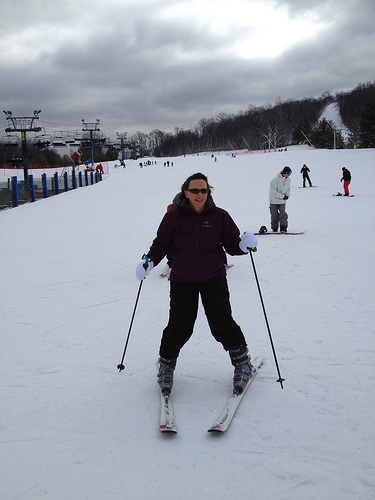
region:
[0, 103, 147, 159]
chair lift at a ski resort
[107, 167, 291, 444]
woman skier with white gloves and sunglasses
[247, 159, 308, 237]
skier with gray pants and white jacket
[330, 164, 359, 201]
skier with red pants and dark jacket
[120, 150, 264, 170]
skiers higher up on the slope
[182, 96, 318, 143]
trees at the side of a ski slope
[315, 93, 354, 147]
steeper slope for more advanced skiers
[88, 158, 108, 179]
skier with red jacket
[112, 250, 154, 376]
black ski pole with white gloved hand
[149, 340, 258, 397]
ski boots in binders on skiis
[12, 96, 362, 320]
skiing at a resort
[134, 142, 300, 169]
all of these people are skiing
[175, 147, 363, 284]
people on slopes having fun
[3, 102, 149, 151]
ski lifts on the resort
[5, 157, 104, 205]
a fence on the slopes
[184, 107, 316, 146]
trees on the mountain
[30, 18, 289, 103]
a cloudy sky above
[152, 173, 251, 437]
she looks happy to be skiing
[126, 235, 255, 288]
she is wearing white gloves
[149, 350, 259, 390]
she has on grey snow boots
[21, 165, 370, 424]
The ground is snow covered.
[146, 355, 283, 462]
Her boots are grey.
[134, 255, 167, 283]
Her glove is white.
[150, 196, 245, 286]
Her jacket is black.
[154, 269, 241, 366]
Her pants are black.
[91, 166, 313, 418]
She has two poles.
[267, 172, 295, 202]
His jacket is white.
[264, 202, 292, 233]
His pants are grey.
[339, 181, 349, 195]
His pants are red.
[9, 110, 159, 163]
The ski lift is above the ground.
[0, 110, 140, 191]
ski lift to the left of skier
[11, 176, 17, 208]
blue metal post next to blue metal post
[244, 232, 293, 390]
skier holding dark ski poles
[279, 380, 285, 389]
sharp point on ski pole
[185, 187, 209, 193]
skier wearing dark sunglasses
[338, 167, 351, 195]
person wearing red snow pants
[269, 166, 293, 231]
person wearing a white jacket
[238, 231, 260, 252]
skier wearing white mittens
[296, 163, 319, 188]
person is snowboarding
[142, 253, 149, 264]
green strap on ski pole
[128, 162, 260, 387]
woman on skis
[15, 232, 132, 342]
white snow on hill side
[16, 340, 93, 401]
white snow on hill side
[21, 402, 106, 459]
white snow on hill side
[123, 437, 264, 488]
white snow on hill side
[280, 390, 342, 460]
white snow on hill side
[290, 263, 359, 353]
white snow on hill side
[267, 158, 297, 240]
person standing in snow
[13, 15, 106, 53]
white clouds in blue sky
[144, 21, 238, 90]
white clouds in blue sky